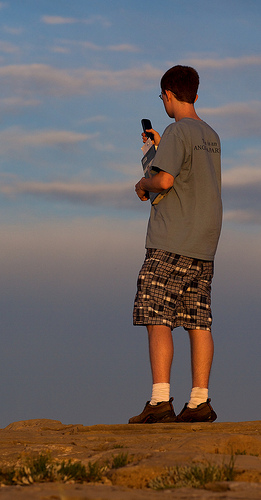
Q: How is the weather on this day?
A: It is cloudy.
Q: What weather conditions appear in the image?
A: It is cloudy.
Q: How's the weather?
A: It is cloudy.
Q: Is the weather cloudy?
A: Yes, it is cloudy.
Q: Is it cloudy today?
A: Yes, it is cloudy.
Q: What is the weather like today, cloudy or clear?
A: It is cloudy.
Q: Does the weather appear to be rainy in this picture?
A: No, it is cloudy.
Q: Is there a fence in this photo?
A: No, there are no fences.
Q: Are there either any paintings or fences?
A: No, there are no fences or paintings.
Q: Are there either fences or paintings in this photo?
A: No, there are no fences or paintings.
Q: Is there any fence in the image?
A: No, there are no fences.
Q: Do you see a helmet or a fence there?
A: No, there are no fences or helmets.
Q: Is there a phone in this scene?
A: Yes, there is a phone.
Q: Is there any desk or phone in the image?
A: Yes, there is a phone.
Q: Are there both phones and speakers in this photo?
A: No, there is a phone but no speakers.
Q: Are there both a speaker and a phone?
A: No, there is a phone but no speakers.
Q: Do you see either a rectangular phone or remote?
A: Yes, there is a rectangular phone.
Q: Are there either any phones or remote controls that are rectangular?
A: Yes, the phone is rectangular.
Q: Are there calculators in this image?
A: No, there are no calculators.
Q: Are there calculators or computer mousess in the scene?
A: No, there are no calculators or computer mousess.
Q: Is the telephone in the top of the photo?
A: Yes, the telephone is in the top of the image.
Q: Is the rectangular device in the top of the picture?
A: Yes, the telephone is in the top of the image.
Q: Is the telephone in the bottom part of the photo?
A: No, the telephone is in the top of the image.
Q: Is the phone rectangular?
A: Yes, the phone is rectangular.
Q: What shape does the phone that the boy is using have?
A: The telephone has rectangular shape.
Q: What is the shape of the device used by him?
A: The telephone is rectangular.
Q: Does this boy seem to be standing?
A: Yes, the boy is standing.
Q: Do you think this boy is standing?
A: Yes, the boy is standing.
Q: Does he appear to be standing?
A: Yes, the boy is standing.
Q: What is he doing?
A: The boy is standing.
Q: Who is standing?
A: The boy is standing.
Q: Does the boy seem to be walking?
A: No, the boy is standing.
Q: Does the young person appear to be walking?
A: No, the boy is standing.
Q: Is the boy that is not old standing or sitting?
A: The boy is standing.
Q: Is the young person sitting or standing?
A: The boy is standing.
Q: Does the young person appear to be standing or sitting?
A: The boy is standing.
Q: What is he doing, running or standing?
A: The boy is standing.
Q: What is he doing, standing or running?
A: The boy is standing.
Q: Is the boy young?
A: Yes, the boy is young.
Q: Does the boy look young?
A: Yes, the boy is young.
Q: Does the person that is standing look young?
A: Yes, the boy is young.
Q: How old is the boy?
A: The boy is young.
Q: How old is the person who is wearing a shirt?
A: The boy is young.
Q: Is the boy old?
A: No, the boy is young.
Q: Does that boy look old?
A: No, the boy is young.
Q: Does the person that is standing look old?
A: No, the boy is young.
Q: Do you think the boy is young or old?
A: The boy is young.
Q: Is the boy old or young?
A: The boy is young.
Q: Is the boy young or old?
A: The boy is young.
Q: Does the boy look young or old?
A: The boy is young.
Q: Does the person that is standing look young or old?
A: The boy is young.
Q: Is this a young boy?
A: Yes, this is a young boy.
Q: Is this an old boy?
A: No, this is a young boy.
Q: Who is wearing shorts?
A: The boy is wearing shorts.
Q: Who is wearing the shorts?
A: The boy is wearing shorts.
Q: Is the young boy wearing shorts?
A: Yes, the boy is wearing shorts.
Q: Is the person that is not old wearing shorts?
A: Yes, the boy is wearing shorts.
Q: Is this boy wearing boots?
A: No, the boy is wearing shorts.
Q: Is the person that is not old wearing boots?
A: No, the boy is wearing shorts.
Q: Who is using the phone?
A: The boy is using the phone.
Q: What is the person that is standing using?
A: The boy is using a phone.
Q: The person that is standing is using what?
A: The boy is using a phone.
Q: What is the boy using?
A: The boy is using a phone.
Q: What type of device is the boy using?
A: The boy is using a phone.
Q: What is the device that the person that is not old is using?
A: The device is a phone.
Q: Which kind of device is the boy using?
A: The boy is using a phone.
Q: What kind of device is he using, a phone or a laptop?
A: The boy is using a phone.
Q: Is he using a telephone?
A: Yes, the boy is using a telephone.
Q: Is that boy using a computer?
A: No, the boy is using a telephone.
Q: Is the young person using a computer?
A: No, the boy is using a telephone.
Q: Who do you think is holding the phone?
A: The boy is holding the phone.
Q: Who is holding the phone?
A: The boy is holding the phone.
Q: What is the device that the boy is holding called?
A: The device is a phone.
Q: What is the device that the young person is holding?
A: The device is a phone.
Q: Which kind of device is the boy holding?
A: The boy is holding the phone.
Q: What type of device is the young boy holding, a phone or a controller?
A: The boy is holding a phone.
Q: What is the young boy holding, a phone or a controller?
A: The boy is holding a phone.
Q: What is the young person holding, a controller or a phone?
A: The boy is holding a phone.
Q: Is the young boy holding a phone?
A: Yes, the boy is holding a phone.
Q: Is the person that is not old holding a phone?
A: Yes, the boy is holding a phone.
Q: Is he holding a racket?
A: No, the boy is holding a phone.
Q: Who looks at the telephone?
A: The boy looks at the telephone.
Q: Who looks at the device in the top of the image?
A: The boy looks at the telephone.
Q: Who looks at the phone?
A: The boy looks at the telephone.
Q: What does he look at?
A: The boy looks at the telephone.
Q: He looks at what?
A: The boy looks at the telephone.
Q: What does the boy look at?
A: The boy looks at the telephone.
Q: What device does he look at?
A: The boy looks at the telephone.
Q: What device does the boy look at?
A: The boy looks at the telephone.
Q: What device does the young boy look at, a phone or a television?
A: The boy looks at a phone.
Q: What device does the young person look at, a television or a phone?
A: The boy looks at a phone.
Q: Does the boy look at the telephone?
A: Yes, the boy looks at the telephone.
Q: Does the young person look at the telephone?
A: Yes, the boy looks at the telephone.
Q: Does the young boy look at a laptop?
A: No, the boy looks at the telephone.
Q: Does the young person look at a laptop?
A: No, the boy looks at the telephone.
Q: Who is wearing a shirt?
A: The boy is wearing a shirt.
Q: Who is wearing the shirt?
A: The boy is wearing a shirt.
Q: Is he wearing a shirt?
A: Yes, the boy is wearing a shirt.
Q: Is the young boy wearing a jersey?
A: No, the boy is wearing a shirt.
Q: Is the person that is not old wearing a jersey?
A: No, the boy is wearing a shirt.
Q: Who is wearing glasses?
A: The boy is wearing glasses.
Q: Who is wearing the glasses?
A: The boy is wearing glasses.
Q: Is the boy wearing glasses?
A: Yes, the boy is wearing glasses.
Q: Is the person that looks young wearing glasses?
A: Yes, the boy is wearing glasses.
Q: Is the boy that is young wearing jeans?
A: No, the boy is wearing glasses.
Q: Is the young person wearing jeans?
A: No, the boy is wearing glasses.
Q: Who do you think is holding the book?
A: The boy is holding the book.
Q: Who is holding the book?
A: The boy is holding the book.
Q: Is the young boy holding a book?
A: Yes, the boy is holding a book.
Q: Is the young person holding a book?
A: Yes, the boy is holding a book.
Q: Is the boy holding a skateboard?
A: No, the boy is holding a book.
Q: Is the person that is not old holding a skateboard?
A: No, the boy is holding a book.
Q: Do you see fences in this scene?
A: No, there are no fences.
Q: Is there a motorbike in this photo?
A: No, there are no motorcycles.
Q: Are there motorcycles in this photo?
A: No, there are no motorcycles.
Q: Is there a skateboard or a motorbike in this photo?
A: No, there are no motorcycles or skateboards.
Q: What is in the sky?
A: The clouds are in the sky.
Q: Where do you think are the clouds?
A: The clouds are in the sky.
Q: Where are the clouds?
A: The clouds are in the sky.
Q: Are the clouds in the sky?
A: Yes, the clouds are in the sky.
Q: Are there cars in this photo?
A: No, there are no cars.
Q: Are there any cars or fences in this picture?
A: No, there are no cars or fences.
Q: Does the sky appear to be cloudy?
A: Yes, the sky is cloudy.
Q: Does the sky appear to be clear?
A: No, the sky is cloudy.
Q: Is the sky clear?
A: No, the sky is cloudy.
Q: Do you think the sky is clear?
A: No, the sky is cloudy.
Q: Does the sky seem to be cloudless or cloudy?
A: The sky is cloudy.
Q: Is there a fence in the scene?
A: No, there are no fences.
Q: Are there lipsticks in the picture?
A: No, there are no lipsticks.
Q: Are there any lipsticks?
A: No, there are no lipsticks.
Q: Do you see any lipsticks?
A: No, there are no lipsticks.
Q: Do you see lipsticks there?
A: No, there are no lipsticks.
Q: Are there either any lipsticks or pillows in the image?
A: No, there are no lipsticks or pillows.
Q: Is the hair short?
A: Yes, the hair is short.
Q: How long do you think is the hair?
A: The hair is short.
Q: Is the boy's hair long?
A: No, the hair is short.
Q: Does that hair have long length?
A: No, the hair is short.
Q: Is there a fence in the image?
A: No, there are no fences.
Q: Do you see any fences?
A: No, there are no fences.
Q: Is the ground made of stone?
A: Yes, the ground is made of stone.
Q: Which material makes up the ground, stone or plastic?
A: The ground is made of stone.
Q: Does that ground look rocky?
A: Yes, the ground is rocky.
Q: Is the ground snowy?
A: No, the ground is rocky.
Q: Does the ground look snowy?
A: No, the ground is rocky.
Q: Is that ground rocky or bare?
A: The ground is rocky.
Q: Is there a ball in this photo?
A: No, there are no balls.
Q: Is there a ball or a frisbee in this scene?
A: No, there are no balls or frisbees.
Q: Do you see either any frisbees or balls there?
A: No, there are no balls or frisbees.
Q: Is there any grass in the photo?
A: Yes, there is grass.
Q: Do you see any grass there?
A: Yes, there is grass.